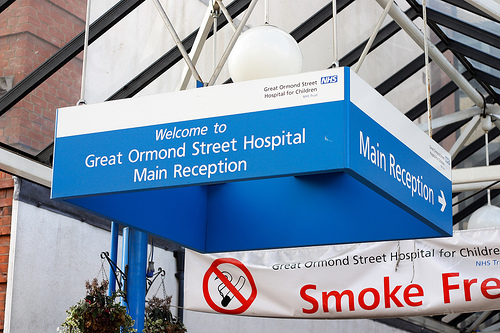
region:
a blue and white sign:
[48, 60, 456, 236]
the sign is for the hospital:
[68, 129, 361, 187]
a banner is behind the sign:
[190, 246, 499, 316]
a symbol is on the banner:
[197, 249, 257, 314]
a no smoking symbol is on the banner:
[201, 255, 256, 317]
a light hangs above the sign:
[217, 3, 304, 83]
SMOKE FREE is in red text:
[288, 268, 495, 305]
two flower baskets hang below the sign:
[63, 250, 188, 331]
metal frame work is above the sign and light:
[8, 3, 496, 140]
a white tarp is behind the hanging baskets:
[19, 203, 184, 330]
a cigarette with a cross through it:
[203, 260, 257, 313]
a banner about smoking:
[183, 236, 498, 318]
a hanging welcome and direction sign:
[56, 80, 465, 247]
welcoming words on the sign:
[80, 117, 308, 179]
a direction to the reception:
[357, 127, 459, 212]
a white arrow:
[432, 185, 449, 214]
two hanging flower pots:
[67, 256, 184, 331]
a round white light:
[223, 22, 302, 84]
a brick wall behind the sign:
[0, 0, 88, 329]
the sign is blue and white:
[43, 84, 400, 269]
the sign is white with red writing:
[204, 242, 324, 312]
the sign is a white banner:
[165, 229, 292, 293]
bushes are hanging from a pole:
[63, 255, 120, 326]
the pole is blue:
[100, 223, 159, 290]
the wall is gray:
[27, 212, 104, 323]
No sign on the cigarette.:
[199, 252, 256, 317]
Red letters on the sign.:
[294, 272, 499, 316]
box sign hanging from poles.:
[43, 63, 456, 258]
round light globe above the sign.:
[225, 20, 308, 87]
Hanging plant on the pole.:
[58, 269, 132, 331]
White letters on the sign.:
[355, 119, 438, 208]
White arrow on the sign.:
[432, 182, 448, 216]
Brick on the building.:
[1, 1, 85, 153]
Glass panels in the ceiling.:
[0, 0, 494, 165]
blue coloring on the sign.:
[48, 106, 453, 256]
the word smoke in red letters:
[300, 276, 423, 313]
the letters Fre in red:
[442, 272, 498, 304]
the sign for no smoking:
[201, 258, 256, 313]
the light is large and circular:
[228, 24, 303, 81]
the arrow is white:
[437, 189, 446, 212]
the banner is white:
[180, 226, 498, 321]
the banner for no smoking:
[185, 225, 499, 319]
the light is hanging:
[226, 0, 301, 82]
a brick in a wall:
[23, 7, 38, 18]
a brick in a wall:
[42, 4, 64, 20]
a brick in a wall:
[34, 11, 56, 28]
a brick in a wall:
[57, 20, 74, 35]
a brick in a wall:
[24, 16, 43, 28]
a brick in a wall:
[37, 29, 54, 46]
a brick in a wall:
[28, 39, 50, 59]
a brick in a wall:
[19, 93, 36, 115]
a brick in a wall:
[14, 112, 30, 127]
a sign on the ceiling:
[48, 63, 399, 240]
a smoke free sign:
[151, 205, 497, 327]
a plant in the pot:
[58, 285, 122, 330]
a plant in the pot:
[128, 295, 177, 330]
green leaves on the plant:
[91, 293, 128, 326]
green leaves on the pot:
[127, 298, 164, 328]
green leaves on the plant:
[155, 310, 175, 330]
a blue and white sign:
[53, 63, 459, 251]